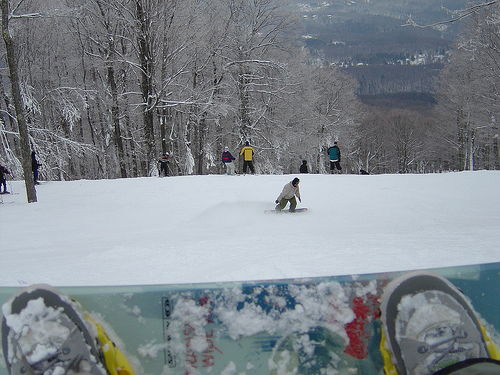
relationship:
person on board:
[273, 177, 304, 212] [262, 207, 311, 213]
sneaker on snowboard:
[381, 270, 499, 373] [1, 254, 498, 373]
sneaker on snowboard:
[0, 285, 134, 372] [1, 254, 498, 373]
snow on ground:
[2, 165, 499, 284] [1, 173, 484, 268]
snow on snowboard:
[150, 281, 354, 357] [1, 254, 498, 373]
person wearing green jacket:
[271, 173, 305, 211] [322, 142, 344, 164]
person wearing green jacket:
[324, 138, 345, 170] [322, 142, 344, 164]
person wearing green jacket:
[235, 139, 259, 171] [322, 142, 344, 164]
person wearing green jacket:
[221, 145, 238, 175] [322, 142, 344, 164]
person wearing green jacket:
[0, 158, 14, 195] [322, 142, 344, 164]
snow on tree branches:
[9, 3, 296, 172] [7, 7, 288, 170]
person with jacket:
[221, 145, 238, 175] [226, 149, 234, 166]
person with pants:
[221, 145, 238, 175] [223, 160, 238, 175]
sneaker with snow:
[0, 285, 134, 372] [449, 307, 464, 322]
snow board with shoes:
[4, 257, 499, 373] [7, 279, 497, 367]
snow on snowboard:
[150, 281, 354, 357] [46, 284, 381, 341]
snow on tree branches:
[2, 165, 499, 284] [187, 14, 304, 121]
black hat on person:
[292, 174, 307, 187] [273, 177, 304, 212]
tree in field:
[388, 112, 429, 178] [11, 73, 499, 169]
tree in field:
[78, 0, 139, 180] [4, 3, 484, 202]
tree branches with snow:
[118, 23, 287, 136] [169, 127, 210, 199]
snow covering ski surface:
[2, 165, 499, 284] [2, 169, 484, 287]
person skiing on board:
[273, 177, 304, 212] [266, 177, 333, 232]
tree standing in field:
[436, 40, 469, 162] [317, 62, 483, 167]